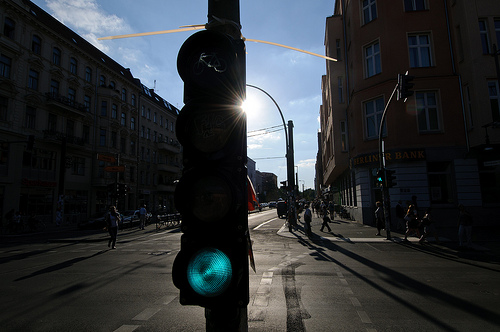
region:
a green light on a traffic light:
[174, 238, 241, 303]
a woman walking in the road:
[101, 193, 128, 254]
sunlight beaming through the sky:
[226, 80, 278, 125]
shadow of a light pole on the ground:
[293, 225, 455, 329]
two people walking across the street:
[400, 196, 444, 251]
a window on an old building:
[80, 63, 100, 86]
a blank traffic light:
[167, 24, 269, 318]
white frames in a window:
[361, 30, 388, 86]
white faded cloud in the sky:
[34, 0, 151, 52]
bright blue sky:
[35, 0, 372, 171]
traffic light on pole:
[161, 33, 248, 305]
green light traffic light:
[165, 236, 234, 300]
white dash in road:
[140, 303, 165, 320]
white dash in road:
[353, 307, 369, 324]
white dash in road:
[348, 295, 367, 308]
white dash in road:
[338, 278, 348, 288]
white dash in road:
[333, 269, 345, 281]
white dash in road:
[156, 292, 183, 306]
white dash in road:
[259, 275, 276, 287]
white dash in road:
[251, 295, 271, 307]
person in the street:
[102, 202, 124, 252]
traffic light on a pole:
[167, 25, 251, 315]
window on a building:
[358, 32, 389, 84]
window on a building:
[359, 87, 390, 142]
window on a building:
[402, 27, 439, 70]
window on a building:
[410, 85, 443, 140]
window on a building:
[349, 0, 388, 27]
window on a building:
[116, 104, 130, 126]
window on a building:
[474, 13, 499, 60]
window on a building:
[450, 74, 498, 136]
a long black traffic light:
[172, 27, 247, 304]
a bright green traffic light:
[183, 245, 233, 292]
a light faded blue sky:
[37, 0, 327, 194]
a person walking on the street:
[105, 199, 122, 251]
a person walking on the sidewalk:
[318, 206, 331, 229]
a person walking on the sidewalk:
[370, 194, 385, 234]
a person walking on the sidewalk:
[402, 198, 415, 238]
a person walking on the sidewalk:
[419, 207, 441, 259]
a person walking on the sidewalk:
[303, 206, 313, 231]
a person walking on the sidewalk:
[328, 196, 337, 221]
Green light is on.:
[160, 27, 250, 305]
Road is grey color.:
[255, 216, 400, 312]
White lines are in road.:
[247, 258, 382, 324]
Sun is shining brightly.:
[236, 84, 266, 132]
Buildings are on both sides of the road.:
[37, 80, 379, 232]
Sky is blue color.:
[127, 4, 193, 42]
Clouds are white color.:
[60, 3, 139, 51]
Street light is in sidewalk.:
[275, 108, 317, 234]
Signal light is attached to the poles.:
[158, 26, 261, 330]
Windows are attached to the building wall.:
[333, 15, 474, 149]